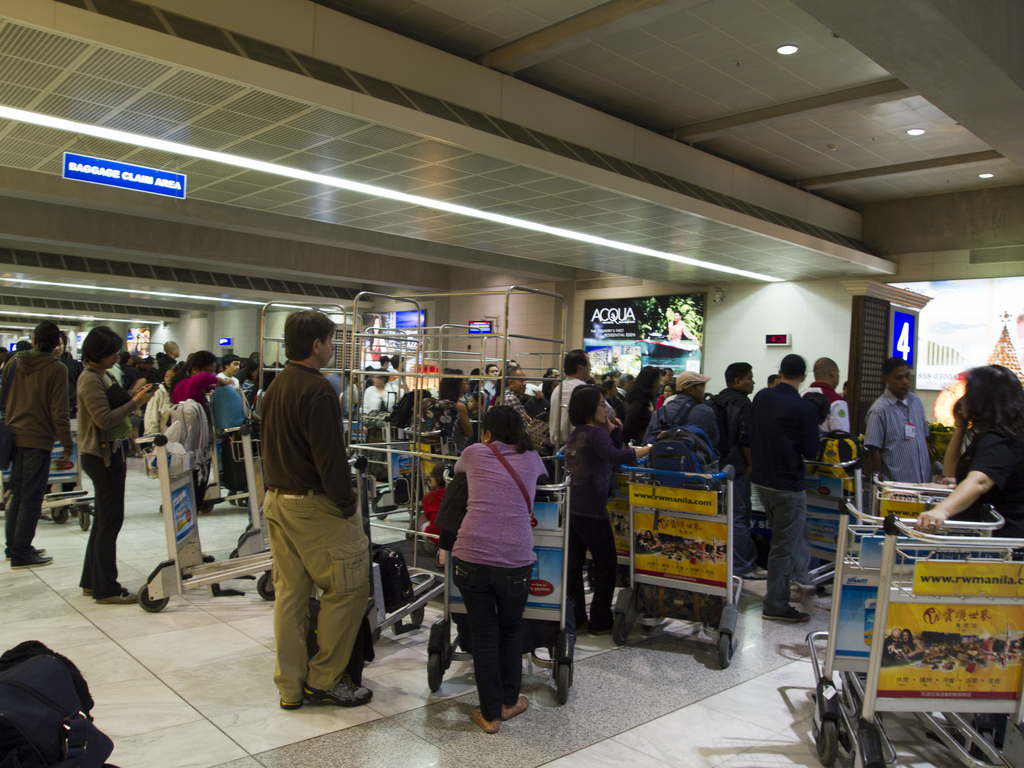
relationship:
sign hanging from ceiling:
[44, 137, 232, 206] [11, 18, 954, 278]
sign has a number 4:
[889, 307, 926, 383] [889, 322, 915, 353]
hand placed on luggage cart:
[906, 500, 948, 535] [800, 484, 993, 757]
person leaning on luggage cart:
[910, 357, 991, 533] [800, 484, 993, 757]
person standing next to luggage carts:
[906, 341, 1023, 557] [869, 580, 1021, 768]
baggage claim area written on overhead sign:
[30, 230, 979, 282] [35, 302, 308, 473]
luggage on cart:
[367, 532, 419, 608] [352, 471, 446, 670]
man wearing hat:
[639, 364, 724, 460] [668, 372, 714, 394]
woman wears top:
[405, 366, 613, 745] [439, 422, 582, 587]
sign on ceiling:
[44, 137, 232, 243] [22, 39, 824, 331]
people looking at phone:
[41, 302, 166, 615] [135, 366, 170, 431]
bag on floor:
[9, 619, 159, 762] [0, 352, 1024, 767]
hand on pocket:
[336, 492, 374, 542] [312, 471, 379, 564]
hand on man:
[336, 492, 374, 542] [230, 271, 390, 736]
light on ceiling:
[22, 85, 816, 328] [22, 9, 936, 362]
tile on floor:
[534, 629, 710, 746] [27, 431, 943, 762]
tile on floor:
[31, 536, 338, 759] [11, 428, 990, 751]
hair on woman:
[463, 398, 546, 453] [431, 376, 598, 750]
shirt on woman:
[444, 437, 566, 595] [433, 363, 591, 739]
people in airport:
[24, 320, 971, 658] [27, 100, 982, 706]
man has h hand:
[250, 303, 384, 712] [336, 491, 363, 541]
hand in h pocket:
[336, 491, 363, 541] [341, 510, 367, 550]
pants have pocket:
[258, 482, 379, 716] [329, 510, 376, 551]